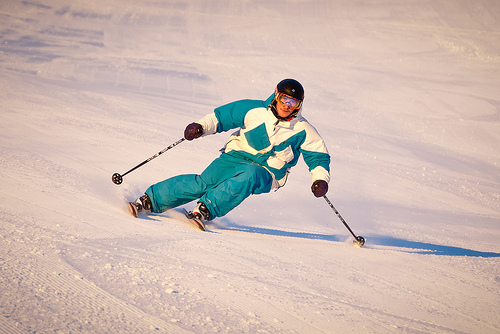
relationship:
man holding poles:
[129, 78, 332, 234] [114, 134, 189, 184]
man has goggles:
[129, 78, 332, 234] [276, 90, 300, 110]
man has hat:
[129, 78, 332, 234] [270, 78, 304, 122]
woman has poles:
[127, 77, 329, 232] [114, 134, 189, 184]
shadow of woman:
[210, 214, 500, 255] [127, 77, 329, 232]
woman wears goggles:
[127, 77, 329, 232] [276, 90, 300, 110]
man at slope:
[129, 78, 332, 234] [85, 58, 488, 333]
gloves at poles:
[185, 122, 203, 142] [114, 134, 189, 184]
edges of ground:
[3, 194, 36, 333] [0, 0, 500, 332]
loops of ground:
[60, 36, 193, 125] [0, 0, 500, 332]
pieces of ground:
[370, 40, 434, 104] [0, 0, 500, 332]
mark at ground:
[125, 55, 209, 81] [0, 0, 500, 332]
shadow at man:
[210, 214, 500, 255] [129, 78, 332, 234]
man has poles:
[129, 78, 332, 234] [114, 134, 189, 184]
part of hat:
[278, 87, 285, 95] [270, 78, 304, 122]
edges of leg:
[240, 189, 248, 198] [197, 162, 277, 218]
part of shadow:
[391, 238, 397, 243] [210, 214, 500, 255]